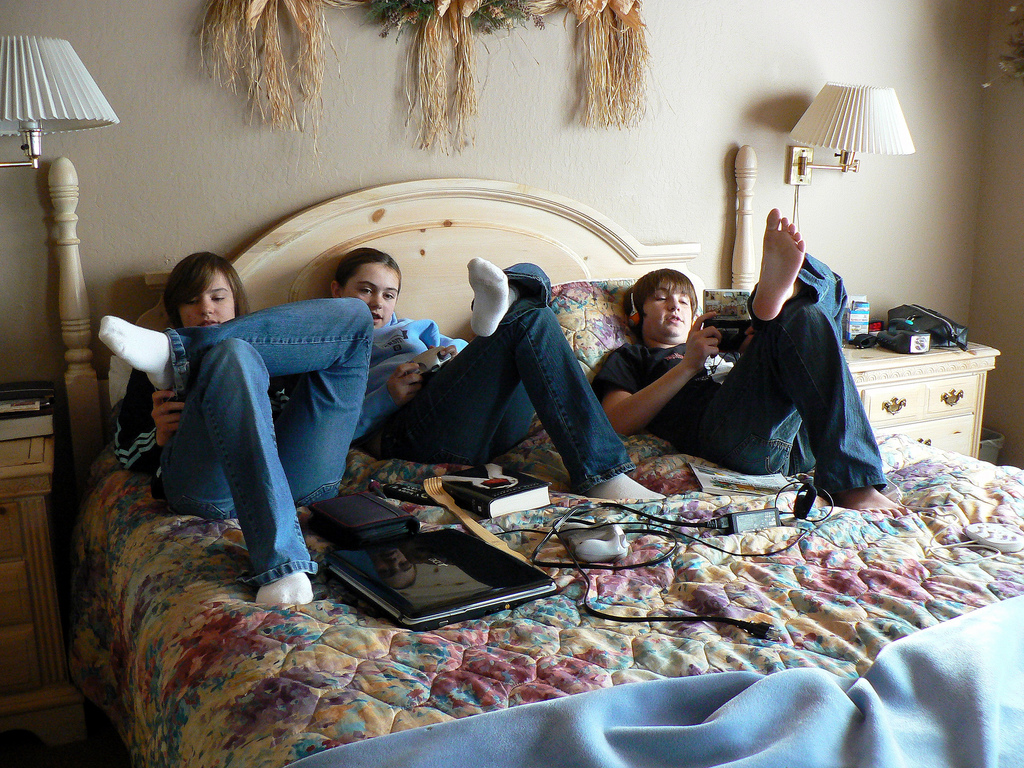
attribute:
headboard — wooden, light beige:
[209, 181, 701, 360]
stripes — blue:
[106, 414, 160, 468]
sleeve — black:
[109, 373, 160, 473]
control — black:
[546, 501, 730, 606]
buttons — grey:
[359, 442, 546, 550]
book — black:
[431, 451, 553, 523]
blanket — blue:
[288, 585, 1021, 765]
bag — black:
[882, 299, 967, 354]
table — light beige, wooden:
[835, 340, 1002, 461]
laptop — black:
[316, 524, 559, 633]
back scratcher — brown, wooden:
[417, 470, 536, 564]